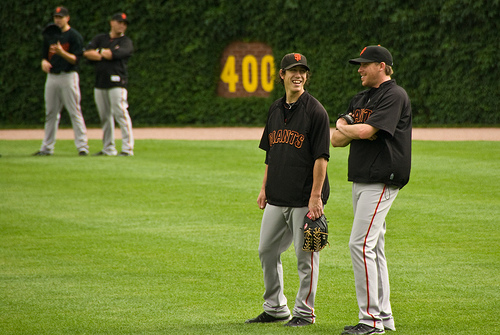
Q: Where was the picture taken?
A: Baseball field.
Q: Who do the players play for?
A: The Giants.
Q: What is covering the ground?
A: Grass.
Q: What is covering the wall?
A: IVY.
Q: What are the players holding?
A: Gloves.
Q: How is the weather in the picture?
A: Sunny.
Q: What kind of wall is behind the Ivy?
A: Brick.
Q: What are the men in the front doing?
A: Talking.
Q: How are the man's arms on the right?
A: Crossed.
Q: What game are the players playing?
A: Baseball.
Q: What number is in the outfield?
A: 400.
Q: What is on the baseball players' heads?
A: Hats.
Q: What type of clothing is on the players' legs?
A: Pants.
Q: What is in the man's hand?
A: A baseball glove.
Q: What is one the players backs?
A: Jerseys.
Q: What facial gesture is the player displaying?
A: A smile.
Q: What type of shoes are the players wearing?
A: Cleats.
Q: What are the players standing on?
A: Grass.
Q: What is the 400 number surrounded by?
A: Plants.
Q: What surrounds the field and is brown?
A: Dirt.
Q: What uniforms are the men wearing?
A: Baseball uniforms.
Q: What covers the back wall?
A: Ivy.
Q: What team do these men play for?
A: San Francisco Giants.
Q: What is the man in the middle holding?
A: Baseball glove.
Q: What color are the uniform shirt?
A: Black.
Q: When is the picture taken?
A: Daytime.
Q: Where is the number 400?
A: In the bushes.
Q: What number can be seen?
A: 400.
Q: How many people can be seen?
A: 4.